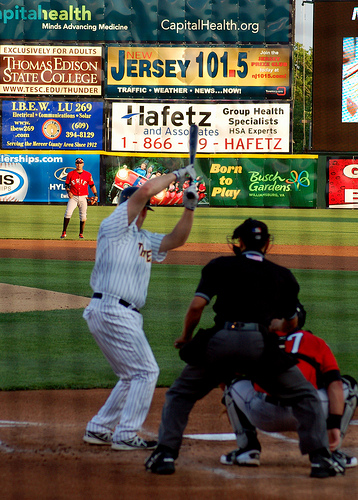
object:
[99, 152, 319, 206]
sign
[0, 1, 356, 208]
fence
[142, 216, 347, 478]
umpire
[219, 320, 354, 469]
player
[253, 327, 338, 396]
red uniform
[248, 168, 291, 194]
busch gardens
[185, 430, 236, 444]
home plate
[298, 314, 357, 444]
catcher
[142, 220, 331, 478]
man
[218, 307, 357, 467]
man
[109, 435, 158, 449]
shoes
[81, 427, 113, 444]
shoes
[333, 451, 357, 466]
shoes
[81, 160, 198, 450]
batter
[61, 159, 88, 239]
infielder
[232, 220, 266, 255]
helmet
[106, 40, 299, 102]
sign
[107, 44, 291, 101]
banner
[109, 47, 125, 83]
letter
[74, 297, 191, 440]
pants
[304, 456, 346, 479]
shoes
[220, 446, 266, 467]
shoes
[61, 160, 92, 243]
man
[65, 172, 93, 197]
red shirt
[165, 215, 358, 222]
shadow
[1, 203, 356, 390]
grass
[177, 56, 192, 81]
letter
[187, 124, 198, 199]
bat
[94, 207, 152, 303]
shirt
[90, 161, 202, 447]
man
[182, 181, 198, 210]
white gloves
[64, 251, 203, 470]
player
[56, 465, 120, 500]
born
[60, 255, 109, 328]
new jersey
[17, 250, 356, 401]
infield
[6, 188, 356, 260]
outfield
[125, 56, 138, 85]
letter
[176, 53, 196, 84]
letter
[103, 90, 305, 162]
sign